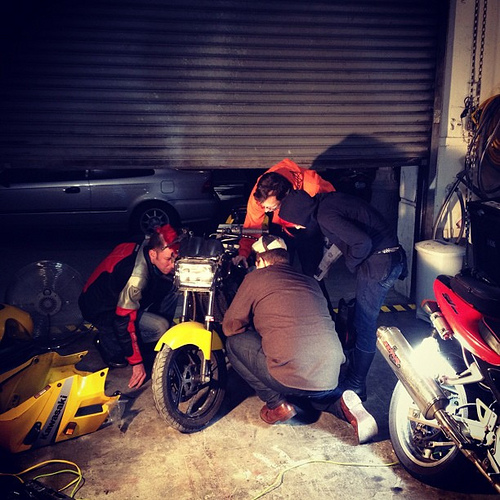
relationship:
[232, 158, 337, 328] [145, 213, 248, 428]
man at motorcycle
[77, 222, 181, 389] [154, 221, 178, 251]
man with mohawk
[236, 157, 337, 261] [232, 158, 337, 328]
red jacket on man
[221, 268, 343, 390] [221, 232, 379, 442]
shirt on man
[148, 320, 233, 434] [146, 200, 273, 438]
wheel on motorcycle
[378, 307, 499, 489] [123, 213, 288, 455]
wheel on motorcycle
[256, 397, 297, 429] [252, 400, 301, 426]
shoe on foot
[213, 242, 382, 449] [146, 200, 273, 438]
man looking at motorcycle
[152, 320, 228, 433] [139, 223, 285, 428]
wheel on motorbike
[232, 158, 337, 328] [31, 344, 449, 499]
man on ground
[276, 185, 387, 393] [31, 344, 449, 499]
man on ground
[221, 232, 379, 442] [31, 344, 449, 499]
man on ground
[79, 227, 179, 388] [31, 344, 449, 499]
man on ground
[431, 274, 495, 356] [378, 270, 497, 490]
red seat on motorcycle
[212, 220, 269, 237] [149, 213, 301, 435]
handlebar on motorcycle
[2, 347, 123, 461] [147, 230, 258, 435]
part on motorcycle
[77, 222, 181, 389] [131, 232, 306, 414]
man looking at motorcycle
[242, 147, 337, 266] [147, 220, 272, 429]
man looking at motorcycle